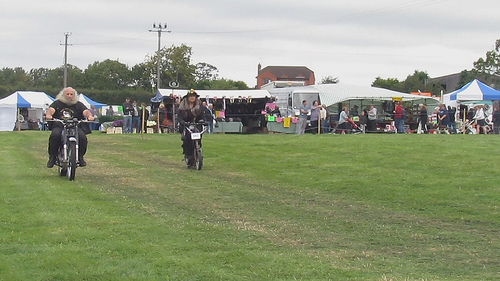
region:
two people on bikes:
[36, 79, 211, 211]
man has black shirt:
[44, 86, 87, 135]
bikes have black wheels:
[59, 143, 89, 179]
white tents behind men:
[171, 74, 397, 115]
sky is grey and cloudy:
[253, 1, 429, 76]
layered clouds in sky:
[236, 14, 402, 86]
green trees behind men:
[1, 46, 251, 91]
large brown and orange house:
[263, 49, 314, 102]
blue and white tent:
[448, 61, 499, 108]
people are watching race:
[241, 91, 419, 133]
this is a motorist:
[33, 74, 95, 174]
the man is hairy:
[54, 91, 65, 98]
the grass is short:
[50, 200, 157, 279]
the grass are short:
[5, 185, 120, 276]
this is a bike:
[187, 125, 207, 157]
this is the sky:
[356, 1, 423, 52]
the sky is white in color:
[320, 0, 422, 47]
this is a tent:
[449, 78, 492, 98]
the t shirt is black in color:
[56, 103, 79, 115]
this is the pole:
[148, 14, 173, 58]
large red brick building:
[254, 63, 315, 88]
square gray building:
[422, 69, 498, 94]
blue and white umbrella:
[442, 78, 497, 100]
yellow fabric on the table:
[282, 116, 289, 125]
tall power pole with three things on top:
[148, 23, 170, 87]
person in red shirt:
[392, 101, 402, 126]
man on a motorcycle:
[43, 85, 95, 165]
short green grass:
[1, 130, 498, 277]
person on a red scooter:
[334, 106, 361, 132]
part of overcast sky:
[2, 2, 499, 86]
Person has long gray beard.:
[51, 85, 98, 120]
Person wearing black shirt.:
[42, 97, 134, 133]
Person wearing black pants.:
[38, 125, 103, 163]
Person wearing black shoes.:
[38, 152, 96, 164]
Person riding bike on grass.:
[31, 88, 96, 185]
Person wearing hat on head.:
[180, 79, 205, 99]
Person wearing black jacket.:
[171, 105, 252, 130]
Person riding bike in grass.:
[166, 129, 238, 197]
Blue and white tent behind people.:
[431, 72, 497, 122]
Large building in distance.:
[243, 52, 335, 89]